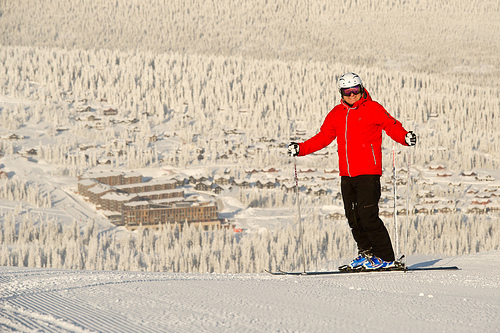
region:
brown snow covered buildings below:
[75, 166, 220, 230]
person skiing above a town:
[264, 72, 460, 279]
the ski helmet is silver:
[337, 73, 362, 88]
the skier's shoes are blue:
[346, 251, 398, 273]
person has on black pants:
[339, 174, 385, 256]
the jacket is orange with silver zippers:
[301, 103, 406, 178]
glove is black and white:
[402, 130, 421, 146]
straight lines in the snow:
[18, 290, 111, 330]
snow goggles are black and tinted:
[338, 85, 362, 96]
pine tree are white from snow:
[62, 227, 208, 272]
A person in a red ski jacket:
[286, 56, 426, 293]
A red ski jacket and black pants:
[313, 63, 411, 226]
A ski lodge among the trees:
[83, 134, 229, 239]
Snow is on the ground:
[144, 284, 409, 329]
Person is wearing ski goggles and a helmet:
[327, 72, 371, 109]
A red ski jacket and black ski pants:
[310, 97, 393, 254]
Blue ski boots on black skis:
[283, 249, 398, 275]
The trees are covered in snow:
[43, 34, 261, 123]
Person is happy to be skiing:
[303, 57, 393, 134]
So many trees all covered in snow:
[71, 35, 281, 116]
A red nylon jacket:
[326, 120, 388, 177]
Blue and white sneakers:
[351, 255, 396, 270]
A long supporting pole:
[288, 160, 313, 279]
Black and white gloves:
[403, 129, 423, 150]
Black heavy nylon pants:
[336, 177, 400, 257]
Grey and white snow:
[173, 278, 392, 330]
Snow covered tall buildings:
[98, 180, 197, 200]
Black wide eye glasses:
[343, 88, 365, 95]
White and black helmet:
[332, 66, 378, 88]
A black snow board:
[408, 266, 465, 274]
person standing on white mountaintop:
[281, 51, 456, 281]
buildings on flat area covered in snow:
[82, 157, 219, 231]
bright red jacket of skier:
[291, 99, 411, 181]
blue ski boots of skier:
[348, 253, 405, 274]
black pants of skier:
[334, 170, 401, 257]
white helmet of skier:
[338, 75, 375, 87]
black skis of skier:
[274, 257, 459, 281]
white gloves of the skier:
[278, 138, 420, 156]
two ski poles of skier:
[285, 134, 415, 269]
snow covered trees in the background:
[11, 42, 491, 254]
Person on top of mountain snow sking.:
[281, 68, 428, 282]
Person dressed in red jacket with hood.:
[297, 86, 409, 176]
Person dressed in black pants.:
[337, 170, 396, 261]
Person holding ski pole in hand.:
[289, 145, 312, 276]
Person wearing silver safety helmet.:
[333, 68, 364, 89]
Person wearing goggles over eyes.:
[336, 83, 366, 95]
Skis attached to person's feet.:
[263, 263, 465, 282]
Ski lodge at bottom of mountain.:
[76, 163, 221, 230]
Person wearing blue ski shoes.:
[341, 253, 405, 271]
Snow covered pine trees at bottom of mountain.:
[35, 220, 255, 270]